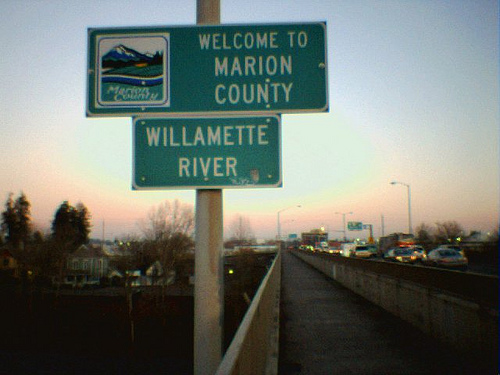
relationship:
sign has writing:
[130, 109, 285, 194] [146, 122, 269, 177]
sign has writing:
[89, 24, 333, 116] [198, 29, 314, 110]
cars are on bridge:
[295, 235, 473, 270] [217, 231, 500, 373]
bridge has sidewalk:
[217, 231, 500, 373] [275, 242, 490, 374]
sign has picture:
[89, 24, 333, 116] [97, 32, 171, 108]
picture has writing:
[97, 32, 171, 108] [107, 83, 165, 105]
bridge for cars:
[217, 231, 500, 373] [295, 235, 473, 270]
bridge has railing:
[217, 231, 500, 373] [207, 238, 283, 372]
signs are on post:
[71, 15, 344, 201] [190, 4, 228, 373]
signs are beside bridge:
[71, 15, 344, 201] [217, 231, 500, 373]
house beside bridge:
[51, 237, 116, 291] [217, 231, 500, 373]